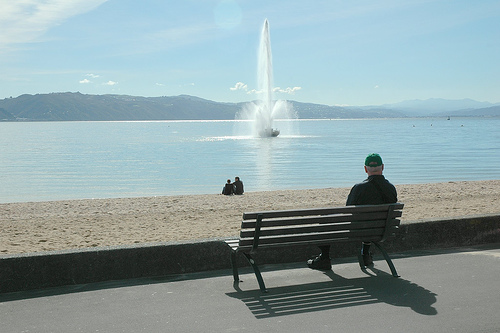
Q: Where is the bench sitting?
A: On concrete.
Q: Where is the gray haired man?
A: Bench.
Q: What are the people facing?
A: Water.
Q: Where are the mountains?
A: Beyond the water.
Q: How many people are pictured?
A: Three.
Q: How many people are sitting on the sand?
A: Two.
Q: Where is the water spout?
A: Middle of water.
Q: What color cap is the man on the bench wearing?
A: Green.